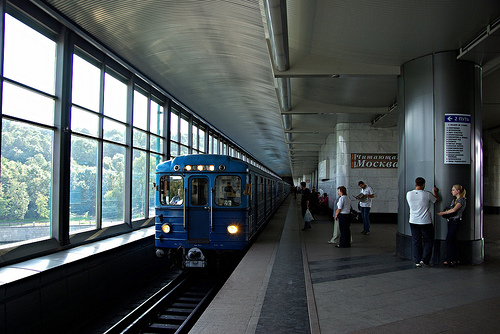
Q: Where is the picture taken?
A: A train station.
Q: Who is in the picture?
A: Travellers.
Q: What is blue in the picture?
A: A train.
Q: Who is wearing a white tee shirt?
A: A man talking to a girl.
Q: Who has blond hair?
A: The girl talking to a man.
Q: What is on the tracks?
A: A train.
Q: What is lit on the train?
A: Headlights.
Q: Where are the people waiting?
A: A platform.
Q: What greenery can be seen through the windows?
A: Trees.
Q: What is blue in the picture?
A: A train.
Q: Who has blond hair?
A: The girl against the pillar.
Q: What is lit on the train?
A: The headlights.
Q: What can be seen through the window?
A: Trees.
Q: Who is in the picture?
A: Travellers.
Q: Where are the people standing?
A: Platform.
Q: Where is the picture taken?
A: A train station.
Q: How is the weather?
A: Sunny and clar.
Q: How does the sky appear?
A: White and bright.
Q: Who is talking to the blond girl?
A: A man in a white shirt.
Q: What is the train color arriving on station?
A: Blue train.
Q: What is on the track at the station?
A: Blue train.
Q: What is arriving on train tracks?
A: Blue train.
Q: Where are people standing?
A: On track.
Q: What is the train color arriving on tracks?
A: Blue train.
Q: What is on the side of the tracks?
A: Windows.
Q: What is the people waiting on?
A: Train.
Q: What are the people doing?
A: Standing.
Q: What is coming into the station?
A: Train.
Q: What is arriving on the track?
A: Train.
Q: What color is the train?
A: Blue.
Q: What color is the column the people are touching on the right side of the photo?
A: Silver.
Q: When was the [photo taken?
A: Daytime.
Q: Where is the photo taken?
A: Train station.